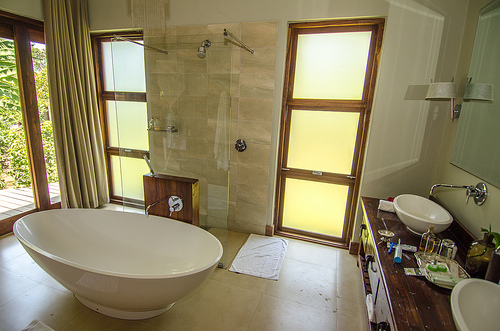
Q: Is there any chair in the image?
A: No, there are no chairs.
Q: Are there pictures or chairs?
A: No, there are no chairs or pictures.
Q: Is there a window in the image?
A: Yes, there is a window.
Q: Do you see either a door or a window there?
A: Yes, there is a window.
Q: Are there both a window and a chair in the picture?
A: No, there is a window but no chairs.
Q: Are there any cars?
A: No, there are no cars.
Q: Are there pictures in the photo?
A: No, there are no pictures.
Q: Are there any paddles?
A: No, there are no paddles.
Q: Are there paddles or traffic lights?
A: No, there are no paddles or traffic lights.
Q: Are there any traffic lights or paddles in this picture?
A: No, there are no paddles or traffic lights.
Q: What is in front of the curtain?
A: The shower is in front of the curtain.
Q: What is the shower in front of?
A: The shower is in front of the curtain.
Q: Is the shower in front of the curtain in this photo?
A: Yes, the shower is in front of the curtain.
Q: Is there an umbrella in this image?
A: No, there are no umbrellas.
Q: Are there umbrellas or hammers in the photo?
A: No, there are no umbrellas or hammers.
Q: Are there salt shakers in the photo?
A: No, there are no salt shakers.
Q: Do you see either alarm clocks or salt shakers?
A: No, there are no salt shakers or alarm clocks.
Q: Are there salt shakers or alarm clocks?
A: No, there are no salt shakers or alarm clocks.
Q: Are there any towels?
A: Yes, there is a towel.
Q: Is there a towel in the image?
A: Yes, there is a towel.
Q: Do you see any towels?
A: Yes, there is a towel.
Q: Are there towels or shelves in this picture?
A: Yes, there is a towel.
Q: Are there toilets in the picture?
A: No, there are no toilets.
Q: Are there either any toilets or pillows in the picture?
A: No, there are no toilets or pillows.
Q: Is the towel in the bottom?
A: Yes, the towel is in the bottom of the image.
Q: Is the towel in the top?
A: No, the towel is in the bottom of the image.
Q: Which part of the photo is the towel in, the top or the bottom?
A: The towel is in the bottom of the image.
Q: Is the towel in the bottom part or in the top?
A: The towel is in the bottom of the image.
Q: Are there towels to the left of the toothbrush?
A: Yes, there is a towel to the left of the toothbrush.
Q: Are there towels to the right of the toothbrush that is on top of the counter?
A: No, the towel is to the left of the toothbrush.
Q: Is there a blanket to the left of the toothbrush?
A: No, there is a towel to the left of the toothbrush.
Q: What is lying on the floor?
A: The towel is lying on the floor.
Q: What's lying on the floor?
A: The towel is lying on the floor.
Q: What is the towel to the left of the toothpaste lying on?
A: The towel is lying on the floor.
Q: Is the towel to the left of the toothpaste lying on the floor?
A: Yes, the towel is lying on the floor.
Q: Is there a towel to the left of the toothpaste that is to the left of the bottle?
A: Yes, there is a towel to the left of the toothpaste.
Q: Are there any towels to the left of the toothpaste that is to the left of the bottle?
A: Yes, there is a towel to the left of the toothpaste.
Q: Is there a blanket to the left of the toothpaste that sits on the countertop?
A: No, there is a towel to the left of the toothpaste.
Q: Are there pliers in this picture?
A: No, there are no pliers.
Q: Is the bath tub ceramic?
A: Yes, the bath tub is ceramic.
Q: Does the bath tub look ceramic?
A: Yes, the bath tub is ceramic.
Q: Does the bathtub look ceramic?
A: Yes, the bathtub is ceramic.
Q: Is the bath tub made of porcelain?
A: Yes, the bath tub is made of porcelain.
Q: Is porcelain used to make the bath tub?
A: Yes, the bath tub is made of porcelain.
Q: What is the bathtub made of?
A: The bathtub is made of porcelain.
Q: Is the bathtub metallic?
A: No, the bathtub is ceramic.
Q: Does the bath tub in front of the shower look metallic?
A: No, the bathtub is ceramic.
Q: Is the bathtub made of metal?
A: No, the bathtub is made of porcelain.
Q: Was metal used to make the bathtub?
A: No, the bathtub is made of porcelain.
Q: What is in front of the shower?
A: The bath tub is in front of the shower.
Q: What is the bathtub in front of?
A: The bathtub is in front of the shower.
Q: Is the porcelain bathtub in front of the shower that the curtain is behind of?
A: Yes, the bathtub is in front of the shower.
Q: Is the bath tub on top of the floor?
A: Yes, the bath tub is on top of the floor.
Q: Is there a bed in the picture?
A: No, there are no beds.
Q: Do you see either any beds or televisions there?
A: No, there are no beds or televisions.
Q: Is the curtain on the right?
A: No, the curtain is on the left of the image.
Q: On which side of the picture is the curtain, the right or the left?
A: The curtain is on the left of the image.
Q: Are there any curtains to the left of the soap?
A: Yes, there is a curtain to the left of the soap.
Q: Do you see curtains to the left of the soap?
A: Yes, there is a curtain to the left of the soap.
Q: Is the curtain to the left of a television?
A: No, the curtain is to the left of a soap.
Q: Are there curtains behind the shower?
A: Yes, there is a curtain behind the shower.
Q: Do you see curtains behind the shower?
A: Yes, there is a curtain behind the shower.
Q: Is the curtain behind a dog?
A: No, the curtain is behind the shower.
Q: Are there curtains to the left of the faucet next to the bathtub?
A: Yes, there is a curtain to the left of the tap.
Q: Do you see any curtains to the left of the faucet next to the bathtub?
A: Yes, there is a curtain to the left of the tap.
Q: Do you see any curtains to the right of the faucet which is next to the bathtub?
A: No, the curtain is to the left of the tap.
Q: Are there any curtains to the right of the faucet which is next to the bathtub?
A: No, the curtain is to the left of the tap.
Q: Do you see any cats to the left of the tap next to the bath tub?
A: No, there is a curtain to the left of the faucet.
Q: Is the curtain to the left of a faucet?
A: Yes, the curtain is to the left of a faucet.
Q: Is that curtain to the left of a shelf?
A: No, the curtain is to the left of a faucet.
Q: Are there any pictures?
A: No, there are no pictures.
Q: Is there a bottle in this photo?
A: Yes, there is a bottle.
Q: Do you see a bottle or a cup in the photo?
A: Yes, there is a bottle.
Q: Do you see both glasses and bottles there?
A: No, there is a bottle but no glasses.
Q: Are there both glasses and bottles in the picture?
A: No, there is a bottle but no glasses.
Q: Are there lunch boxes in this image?
A: No, there are no lunch boxes.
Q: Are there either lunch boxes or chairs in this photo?
A: No, there are no lunch boxes or chairs.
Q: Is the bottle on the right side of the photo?
A: Yes, the bottle is on the right of the image.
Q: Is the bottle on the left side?
A: No, the bottle is on the right of the image.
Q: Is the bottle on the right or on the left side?
A: The bottle is on the right of the image.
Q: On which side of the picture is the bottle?
A: The bottle is on the right of the image.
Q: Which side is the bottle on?
A: The bottle is on the right of the image.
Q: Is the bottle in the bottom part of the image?
A: Yes, the bottle is in the bottom of the image.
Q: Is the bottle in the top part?
A: No, the bottle is in the bottom of the image.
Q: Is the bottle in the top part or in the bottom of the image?
A: The bottle is in the bottom of the image.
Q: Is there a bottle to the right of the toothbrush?
A: Yes, there is a bottle to the right of the toothbrush.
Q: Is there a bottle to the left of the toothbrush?
A: No, the bottle is to the right of the toothbrush.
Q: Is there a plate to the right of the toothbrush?
A: No, there is a bottle to the right of the toothbrush.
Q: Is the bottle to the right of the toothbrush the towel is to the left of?
A: Yes, the bottle is to the right of the toothbrush.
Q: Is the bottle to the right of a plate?
A: No, the bottle is to the right of the toothbrush.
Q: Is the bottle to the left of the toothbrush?
A: No, the bottle is to the right of the toothbrush.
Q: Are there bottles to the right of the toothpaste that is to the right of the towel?
A: Yes, there is a bottle to the right of the toothpaste.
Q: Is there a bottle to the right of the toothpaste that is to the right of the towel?
A: Yes, there is a bottle to the right of the toothpaste.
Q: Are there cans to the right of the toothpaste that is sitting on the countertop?
A: No, there is a bottle to the right of the toothpaste.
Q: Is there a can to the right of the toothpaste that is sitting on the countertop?
A: No, there is a bottle to the right of the toothpaste.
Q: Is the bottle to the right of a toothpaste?
A: Yes, the bottle is to the right of a toothpaste.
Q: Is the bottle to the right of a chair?
A: No, the bottle is to the right of a toothpaste.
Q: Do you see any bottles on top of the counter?
A: Yes, there is a bottle on top of the counter.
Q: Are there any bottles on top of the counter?
A: Yes, there is a bottle on top of the counter.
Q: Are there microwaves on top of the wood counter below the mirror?
A: No, there is a bottle on top of the counter.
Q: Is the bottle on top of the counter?
A: Yes, the bottle is on top of the counter.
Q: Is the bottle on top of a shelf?
A: No, the bottle is on top of the counter.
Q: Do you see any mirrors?
A: Yes, there is a mirror.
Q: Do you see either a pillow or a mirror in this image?
A: Yes, there is a mirror.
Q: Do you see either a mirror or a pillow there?
A: Yes, there is a mirror.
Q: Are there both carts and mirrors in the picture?
A: No, there is a mirror but no carts.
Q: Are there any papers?
A: No, there are no papers.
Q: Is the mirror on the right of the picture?
A: Yes, the mirror is on the right of the image.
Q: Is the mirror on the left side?
A: No, the mirror is on the right of the image.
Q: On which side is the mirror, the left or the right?
A: The mirror is on the right of the image.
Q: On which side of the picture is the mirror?
A: The mirror is on the right of the image.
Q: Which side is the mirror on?
A: The mirror is on the right of the image.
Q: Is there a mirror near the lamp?
A: Yes, there is a mirror near the lamp.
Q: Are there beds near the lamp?
A: No, there is a mirror near the lamp.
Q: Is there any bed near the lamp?
A: No, there is a mirror near the lamp.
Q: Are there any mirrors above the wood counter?
A: Yes, there is a mirror above the counter.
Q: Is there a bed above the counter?
A: No, there is a mirror above the counter.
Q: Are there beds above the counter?
A: No, there is a mirror above the counter.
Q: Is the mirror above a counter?
A: Yes, the mirror is above a counter.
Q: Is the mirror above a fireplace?
A: No, the mirror is above a counter.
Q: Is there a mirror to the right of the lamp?
A: Yes, there is a mirror to the right of the lamp.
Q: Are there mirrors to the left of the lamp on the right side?
A: No, the mirror is to the right of the lamp.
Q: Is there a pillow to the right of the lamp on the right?
A: No, there is a mirror to the right of the lamp.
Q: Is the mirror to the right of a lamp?
A: Yes, the mirror is to the right of a lamp.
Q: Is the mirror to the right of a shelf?
A: No, the mirror is to the right of a lamp.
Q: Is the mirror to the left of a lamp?
A: No, the mirror is to the right of a lamp.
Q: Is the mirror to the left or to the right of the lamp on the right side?
A: The mirror is to the right of the lamp.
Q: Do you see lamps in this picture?
A: Yes, there is a lamp.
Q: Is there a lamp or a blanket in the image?
A: Yes, there is a lamp.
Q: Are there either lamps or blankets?
A: Yes, there is a lamp.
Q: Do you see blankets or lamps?
A: Yes, there is a lamp.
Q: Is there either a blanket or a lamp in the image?
A: Yes, there is a lamp.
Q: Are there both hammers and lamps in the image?
A: No, there is a lamp but no hammers.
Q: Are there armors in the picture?
A: No, there are no armors.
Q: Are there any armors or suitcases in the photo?
A: No, there are no armors or suitcases.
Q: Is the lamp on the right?
A: Yes, the lamp is on the right of the image.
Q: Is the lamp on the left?
A: No, the lamp is on the right of the image.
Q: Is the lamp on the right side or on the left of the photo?
A: The lamp is on the right of the image.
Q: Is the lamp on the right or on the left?
A: The lamp is on the right of the image.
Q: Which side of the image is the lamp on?
A: The lamp is on the right of the image.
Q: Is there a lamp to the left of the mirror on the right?
A: Yes, there is a lamp to the left of the mirror.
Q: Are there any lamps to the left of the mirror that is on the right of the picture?
A: Yes, there is a lamp to the left of the mirror.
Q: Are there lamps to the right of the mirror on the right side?
A: No, the lamp is to the left of the mirror.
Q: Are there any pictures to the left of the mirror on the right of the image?
A: No, there is a lamp to the left of the mirror.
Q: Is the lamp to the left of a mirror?
A: Yes, the lamp is to the left of a mirror.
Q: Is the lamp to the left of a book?
A: No, the lamp is to the left of a mirror.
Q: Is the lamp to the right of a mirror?
A: No, the lamp is to the left of a mirror.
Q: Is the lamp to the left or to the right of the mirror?
A: The lamp is to the left of the mirror.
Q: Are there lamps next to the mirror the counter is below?
A: Yes, there is a lamp next to the mirror.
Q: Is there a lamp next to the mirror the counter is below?
A: Yes, there is a lamp next to the mirror.